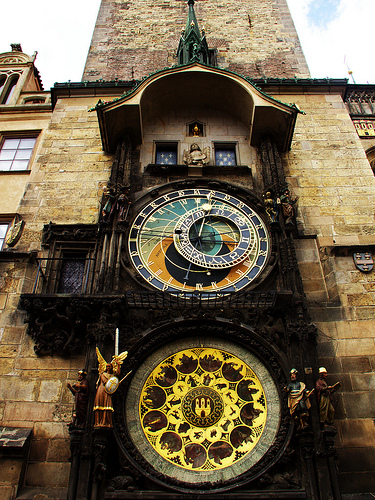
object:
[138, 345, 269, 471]
clock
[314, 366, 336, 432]
person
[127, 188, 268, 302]
clock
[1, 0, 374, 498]
building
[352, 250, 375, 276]
shield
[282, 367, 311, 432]
statue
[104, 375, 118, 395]
shield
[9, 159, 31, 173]
window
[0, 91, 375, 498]
castel`s wall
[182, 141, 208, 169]
man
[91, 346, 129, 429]
person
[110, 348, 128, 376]
wing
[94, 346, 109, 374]
wing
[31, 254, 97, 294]
fence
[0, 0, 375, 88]
sky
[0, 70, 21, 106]
door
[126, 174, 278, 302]
clock faces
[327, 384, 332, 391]
hand